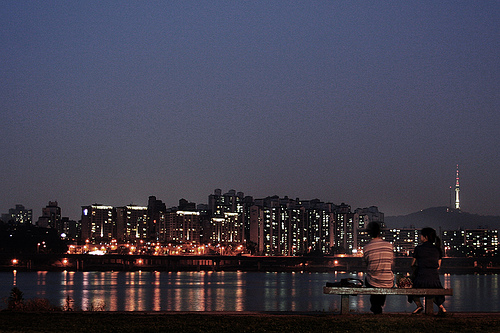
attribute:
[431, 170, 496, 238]
tower — white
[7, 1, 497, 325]
night — romantic